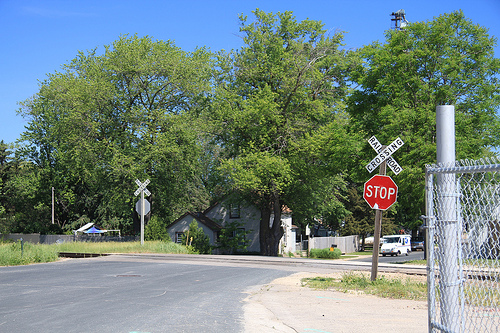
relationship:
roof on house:
[190, 206, 226, 234] [169, 197, 301, 262]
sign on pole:
[361, 130, 412, 180] [373, 160, 382, 293]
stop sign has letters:
[366, 173, 402, 212] [367, 183, 399, 197]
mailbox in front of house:
[329, 243, 344, 250] [169, 197, 301, 262]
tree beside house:
[232, 67, 312, 259] [169, 197, 301, 262]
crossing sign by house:
[126, 174, 157, 200] [169, 197, 301, 262]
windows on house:
[224, 199, 246, 223] [169, 197, 301, 262]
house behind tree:
[169, 197, 301, 262] [232, 67, 312, 259]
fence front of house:
[427, 166, 490, 332] [169, 197, 301, 262]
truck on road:
[373, 232, 418, 258] [341, 249, 415, 271]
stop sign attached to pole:
[366, 173, 402, 212] [373, 160, 382, 293]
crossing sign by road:
[361, 130, 412, 180] [185, 253, 364, 271]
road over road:
[185, 253, 364, 271] [341, 249, 415, 271]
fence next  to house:
[427, 166, 490, 332] [169, 197, 301, 262]